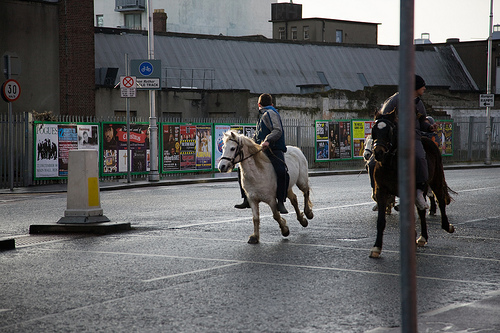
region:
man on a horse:
[197, 92, 344, 253]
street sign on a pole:
[127, 49, 173, 180]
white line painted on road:
[142, 255, 242, 297]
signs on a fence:
[171, 121, 221, 171]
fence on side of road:
[461, 114, 498, 156]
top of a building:
[283, 8, 385, 59]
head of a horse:
[343, 114, 394, 181]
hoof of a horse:
[361, 238, 383, 263]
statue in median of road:
[22, 141, 136, 243]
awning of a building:
[158, 33, 368, 110]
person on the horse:
[212, 88, 316, 242]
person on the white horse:
[214, 94, 317, 250]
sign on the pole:
[120, 75, 137, 95]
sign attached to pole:
[1, 75, 23, 105]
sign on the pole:
[478, 90, 493, 107]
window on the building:
[303, 26, 310, 38]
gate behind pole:
[32, 113, 148, 184]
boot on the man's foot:
[278, 202, 289, 213]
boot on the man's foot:
[233, 199, 255, 214]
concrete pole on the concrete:
[61, 149, 106, 226]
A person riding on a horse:
[214, 78, 324, 248]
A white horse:
[213, 132, 317, 252]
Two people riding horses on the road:
[210, 69, 467, 267]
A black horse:
[368, 111, 454, 258]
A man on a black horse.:
[355, 75, 466, 263]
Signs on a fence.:
[28, 117, 456, 169]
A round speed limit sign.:
[3, 77, 25, 106]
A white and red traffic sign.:
[116, 71, 136, 99]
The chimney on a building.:
[152, 6, 172, 33]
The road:
[0, 161, 498, 331]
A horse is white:
[213, 127, 319, 247]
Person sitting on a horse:
[213, 87, 318, 245]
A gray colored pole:
[395, 38, 423, 331]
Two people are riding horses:
[212, 70, 462, 262]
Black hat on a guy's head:
[412, 70, 427, 101]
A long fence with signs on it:
[3, 112, 498, 188]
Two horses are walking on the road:
[2, 72, 498, 329]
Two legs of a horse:
[244, 200, 294, 248]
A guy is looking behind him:
[247, 90, 287, 135]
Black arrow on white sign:
[474, 90, 496, 111]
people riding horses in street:
[167, 39, 478, 296]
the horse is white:
[208, 56, 327, 271]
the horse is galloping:
[194, 56, 332, 268]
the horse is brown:
[373, 43, 484, 259]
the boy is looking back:
[336, 43, 496, 233]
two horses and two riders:
[161, 48, 498, 276]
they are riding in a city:
[56, 20, 497, 282]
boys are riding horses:
[188, 40, 450, 299]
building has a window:
[301, 26, 310, 37]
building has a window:
[293, 25, 298, 39]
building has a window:
[336, 29, 342, 41]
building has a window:
[278, 29, 285, 41]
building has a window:
[164, 110, 182, 120]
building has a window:
[116, 109, 136, 119]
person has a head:
[413, 76, 425, 94]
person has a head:
[256, 91, 273, 110]